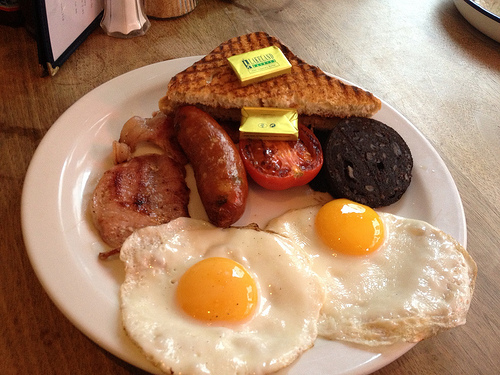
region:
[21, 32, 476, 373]
a white plate with breakfast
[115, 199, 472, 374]
two fried eggs sunny-side up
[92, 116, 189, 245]
a piece of bacon on the plate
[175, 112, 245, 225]
a sausage link on the plate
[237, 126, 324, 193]
1/2 of a plum tomato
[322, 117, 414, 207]
a small round piece of brown bread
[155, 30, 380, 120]
toast cut into a triangle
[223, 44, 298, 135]
two pats of butter in gold wrapper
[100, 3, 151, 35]
a clear glass salt shaker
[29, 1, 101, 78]
the menu next to the salt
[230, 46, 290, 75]
Butter on top of toast.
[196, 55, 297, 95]
Piece of toast under butter.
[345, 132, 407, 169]
Dark colored bread on plate.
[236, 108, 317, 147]
Butter sitting on top of tomato.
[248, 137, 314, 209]
Tomato on top of plate.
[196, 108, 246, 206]
Piece of brown sausage on plate.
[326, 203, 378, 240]
Yellow yolk on egg.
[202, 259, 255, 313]
Yellow yolk on egg.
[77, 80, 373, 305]
Food on top of white plate.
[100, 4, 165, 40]
Salt shaker sitting on table.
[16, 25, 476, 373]
plate of breakfast food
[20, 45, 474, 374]
round white plate with food on top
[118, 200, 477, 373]
two eggs fried sunny-side up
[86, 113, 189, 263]
slice of fried ham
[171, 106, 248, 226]
piece of fried sausage link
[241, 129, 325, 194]
tomato half on plate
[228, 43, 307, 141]
two pats of butter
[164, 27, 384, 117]
piece of toast with butter on top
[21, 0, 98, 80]
menu propped up on table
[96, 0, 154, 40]
salt shaker on table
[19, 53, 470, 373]
a round white plate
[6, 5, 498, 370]
a wooden table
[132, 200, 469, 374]
two fried eggs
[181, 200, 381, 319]
two yellow egg yolks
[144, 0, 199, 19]
a gray pepper shaker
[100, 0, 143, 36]
a salt shaker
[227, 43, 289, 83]
some butter on the toast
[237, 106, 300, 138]
butter on a tomato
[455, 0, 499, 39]
part of a white bowl with blue trim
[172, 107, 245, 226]
a piece of sausage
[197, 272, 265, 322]
Yellow yolk on egg.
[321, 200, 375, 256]
Yellow yolk on egg.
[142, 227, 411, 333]
2 eggs on white plate.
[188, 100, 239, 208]
Brown sausage on white plate.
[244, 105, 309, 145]
Butter packet on top of tomato.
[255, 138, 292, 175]
Red tomato on white plate.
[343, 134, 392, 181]
Dark piece of bread.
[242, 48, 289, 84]
Butter packet on top of bread.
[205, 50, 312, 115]
Piece of toast on top of plate.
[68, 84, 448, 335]
White plate sitting on top of brown table.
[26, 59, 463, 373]
a plate made for dining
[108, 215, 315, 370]
an egg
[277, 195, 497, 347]
an egg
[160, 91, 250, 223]
a yummy hunk of meat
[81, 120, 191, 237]
a yummy hunk of meat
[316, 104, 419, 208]
a yummy hunk of meat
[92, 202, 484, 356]
Two eggs over easy on the plate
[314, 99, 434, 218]
Blood pudding on the plate next to the toast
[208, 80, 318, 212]
Tomato in the middle of the plate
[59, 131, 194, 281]
English bacon on the left hand side of the plate